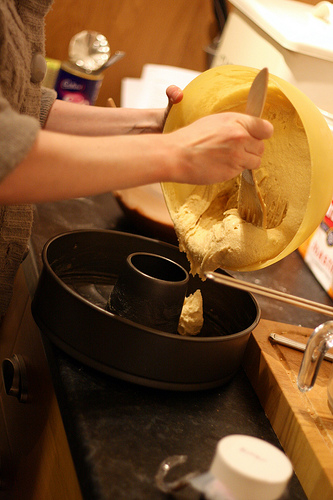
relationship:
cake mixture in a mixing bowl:
[175, 85, 312, 340] [158, 61, 332, 272]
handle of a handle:
[297, 316, 332, 396] [296, 317, 332, 392]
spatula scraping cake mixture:
[236, 65, 272, 232] [175, 85, 312, 340]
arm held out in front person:
[4, 109, 277, 206] [2, 0, 276, 323]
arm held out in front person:
[23, 80, 183, 145] [2, 0, 276, 323]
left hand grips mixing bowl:
[160, 79, 187, 128] [156, 61, 332, 275]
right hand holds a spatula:
[160, 108, 276, 187] [236, 65, 272, 232]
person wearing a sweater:
[2, 0, 276, 323] [1, 1, 59, 331]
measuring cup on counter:
[182, 431, 296, 499] [21, 135, 332, 499]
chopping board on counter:
[234, 312, 333, 498] [21, 135, 332, 499]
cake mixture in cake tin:
[175, 85, 312, 340] [27, 224, 265, 401]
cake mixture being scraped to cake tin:
[175, 85, 312, 340] [27, 224, 265, 401]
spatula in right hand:
[236, 65, 272, 232] [160, 108, 276, 187]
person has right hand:
[2, 0, 276, 323] [160, 108, 276, 187]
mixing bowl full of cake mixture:
[158, 61, 332, 272] [175, 85, 312, 340]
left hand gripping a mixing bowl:
[160, 79, 187, 128] [156, 61, 332, 275]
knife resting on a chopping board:
[265, 329, 333, 371] [234, 312, 333, 498]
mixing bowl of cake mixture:
[156, 61, 332, 275] [175, 85, 312, 340]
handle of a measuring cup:
[155, 449, 205, 491] [182, 431, 296, 499]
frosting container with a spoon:
[49, 28, 111, 107] [92, 49, 126, 79]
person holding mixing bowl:
[2, 0, 276, 323] [156, 61, 332, 275]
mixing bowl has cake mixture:
[156, 61, 332, 275] [175, 85, 312, 340]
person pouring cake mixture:
[2, 0, 276, 323] [175, 85, 312, 340]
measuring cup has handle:
[182, 431, 296, 499] [297, 316, 332, 396]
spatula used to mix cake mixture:
[236, 65, 272, 232] [175, 85, 312, 340]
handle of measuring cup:
[155, 449, 205, 491] [182, 431, 296, 499]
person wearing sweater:
[2, 0, 276, 323] [1, 1, 59, 331]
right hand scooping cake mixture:
[160, 108, 276, 187] [175, 85, 312, 340]